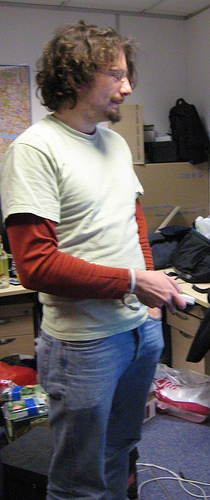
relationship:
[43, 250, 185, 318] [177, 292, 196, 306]
hand holding remote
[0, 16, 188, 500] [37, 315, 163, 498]
man wearing blue jeans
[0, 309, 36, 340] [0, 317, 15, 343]
drawer with handles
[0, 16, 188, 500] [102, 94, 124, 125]
man with facial goatee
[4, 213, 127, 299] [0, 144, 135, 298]
red sleeve covering an arm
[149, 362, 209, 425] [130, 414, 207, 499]
plastic bag on floor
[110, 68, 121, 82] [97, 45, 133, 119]
glasses on a face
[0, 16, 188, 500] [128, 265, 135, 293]
man wearing wristband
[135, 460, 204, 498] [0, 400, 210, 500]
cord on carpet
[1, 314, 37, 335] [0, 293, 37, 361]
drawer on cabinet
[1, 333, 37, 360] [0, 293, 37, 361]
drawer on cabinet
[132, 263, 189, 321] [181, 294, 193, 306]
hand holding remote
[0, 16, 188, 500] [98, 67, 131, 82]
man wearing glasses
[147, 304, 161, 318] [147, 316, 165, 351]
hand in pocket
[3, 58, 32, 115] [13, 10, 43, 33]
map on wall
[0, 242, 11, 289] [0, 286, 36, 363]
bottle on desk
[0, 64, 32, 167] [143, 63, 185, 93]
map on wall